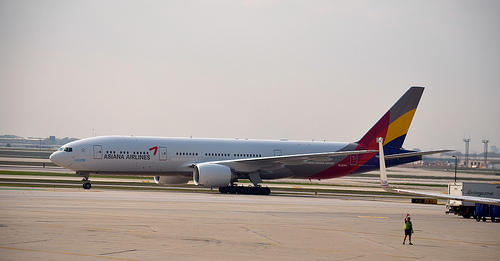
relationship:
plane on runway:
[48, 86, 456, 196] [0, 148, 500, 260]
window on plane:
[120, 151, 123, 154] [48, 86, 456, 196]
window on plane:
[106, 151, 109, 153] [48, 86, 456, 196]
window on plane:
[110, 151, 112, 153] [48, 86, 456, 196]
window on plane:
[113, 151, 114, 153] [48, 86, 456, 196]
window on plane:
[124, 151, 126, 153] [48, 86, 456, 196]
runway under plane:
[0, 148, 500, 260] [48, 86, 456, 196]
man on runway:
[402, 213, 415, 245] [0, 148, 500, 260]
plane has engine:
[48, 86, 456, 196] [193, 163, 241, 187]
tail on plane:
[356, 85, 427, 152] [48, 86, 456, 196]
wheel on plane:
[82, 180, 94, 190] [48, 86, 456, 196]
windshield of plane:
[58, 147, 73, 152] [48, 86, 456, 196]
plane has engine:
[48, 86, 456, 196] [154, 176, 193, 185]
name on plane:
[103, 152, 151, 160] [48, 86, 456, 196]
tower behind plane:
[464, 134, 472, 165] [48, 86, 456, 196]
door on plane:
[93, 144, 102, 159] [48, 86, 456, 196]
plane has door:
[48, 86, 456, 196] [93, 144, 102, 159]